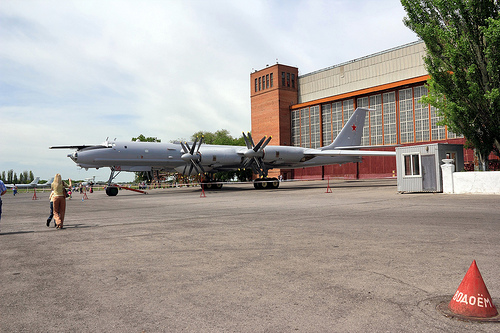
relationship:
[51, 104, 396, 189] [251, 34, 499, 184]
airplane in front of building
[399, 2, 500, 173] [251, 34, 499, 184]
tree in front of building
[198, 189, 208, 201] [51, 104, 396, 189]
red triangle to left of airplane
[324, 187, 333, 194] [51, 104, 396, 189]
red triangle to left of airplane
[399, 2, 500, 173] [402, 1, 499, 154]
tree has leaves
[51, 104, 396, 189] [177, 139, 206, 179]
airplane has a propeller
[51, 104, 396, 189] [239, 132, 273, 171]
airplane has propeller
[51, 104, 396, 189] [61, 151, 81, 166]
airplane has propeller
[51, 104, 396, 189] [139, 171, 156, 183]
airplane has propeller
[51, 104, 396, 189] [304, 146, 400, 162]
airplane has a wing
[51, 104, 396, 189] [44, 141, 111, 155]
airplane has a wing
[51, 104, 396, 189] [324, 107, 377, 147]
airplane has a wing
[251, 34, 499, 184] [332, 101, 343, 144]
building has a window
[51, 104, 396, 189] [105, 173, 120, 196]
airplane has landing gear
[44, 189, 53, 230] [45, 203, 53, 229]
person wearing jeans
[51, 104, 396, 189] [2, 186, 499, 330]
airplane sitting in parking lot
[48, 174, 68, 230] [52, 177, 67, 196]
woman has hair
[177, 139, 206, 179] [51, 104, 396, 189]
propeller at front left airplane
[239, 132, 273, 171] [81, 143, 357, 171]
propeller next to airplane body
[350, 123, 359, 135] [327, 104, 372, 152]
star on back tail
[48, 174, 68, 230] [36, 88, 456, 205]
woman taking picture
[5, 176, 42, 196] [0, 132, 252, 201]
airplane in background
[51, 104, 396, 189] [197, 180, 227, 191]
airplane has wheels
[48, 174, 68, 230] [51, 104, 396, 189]
woman in front of airplane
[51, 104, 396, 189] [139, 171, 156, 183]
airplane has a propeller